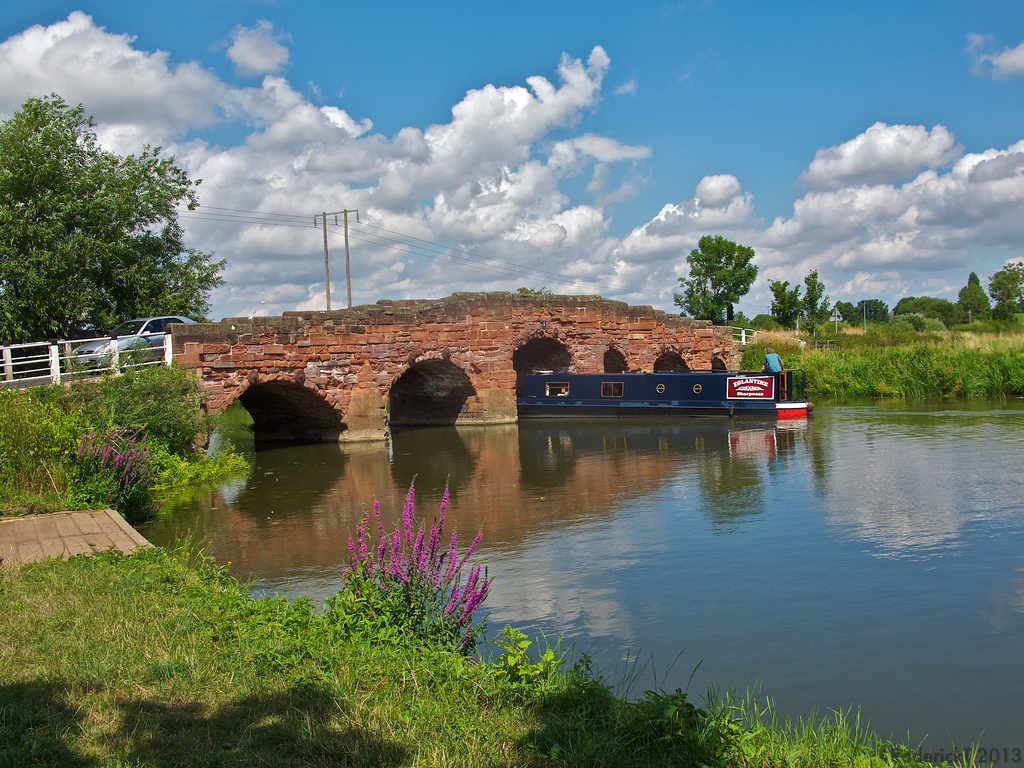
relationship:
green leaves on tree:
[109, 212, 152, 261] [1, 84, 235, 356]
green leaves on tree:
[121, 263, 176, 322] [1, 84, 235, 356]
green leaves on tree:
[48, 218, 100, 296] [1, 84, 235, 356]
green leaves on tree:
[114, 238, 165, 322] [1, 84, 235, 356]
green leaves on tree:
[112, 121, 182, 195] [1, 84, 235, 356]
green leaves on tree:
[691, 244, 720, 289] [674, 228, 755, 326]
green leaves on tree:
[691, 231, 736, 301] [686, 226, 760, 328]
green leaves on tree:
[751, 269, 819, 324] [760, 267, 833, 329]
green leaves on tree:
[855, 294, 887, 327] [852, 295, 888, 330]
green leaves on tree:
[946, 257, 1007, 337] [950, 272, 998, 345]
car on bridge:
[70, 307, 198, 366] [150, 283, 752, 451]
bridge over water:
[150, 283, 752, 451] [131, 403, 1020, 626]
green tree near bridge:
[4, 90, 201, 326] [150, 283, 752, 451]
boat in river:
[522, 361, 813, 431] [131, 408, 1023, 758]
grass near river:
[4, 364, 962, 763] [130, 408, 1022, 738]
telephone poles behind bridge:
[310, 200, 368, 300] [157, 285, 761, 470]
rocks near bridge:
[315, 332, 392, 377] [150, 283, 752, 451]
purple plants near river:
[329, 474, 495, 630] [98, 419, 1022, 691]